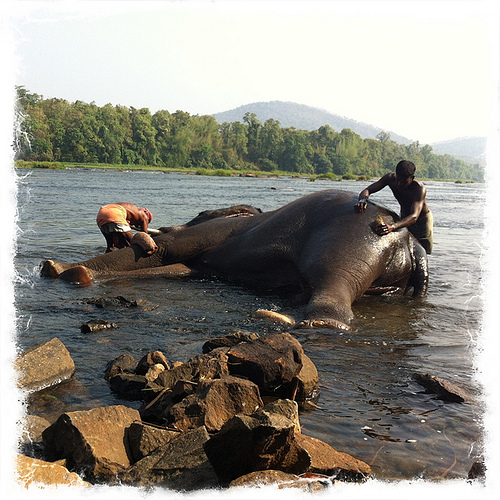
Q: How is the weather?
A: It is clear.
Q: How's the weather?
A: It is clear.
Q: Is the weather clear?
A: Yes, it is clear.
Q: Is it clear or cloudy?
A: It is clear.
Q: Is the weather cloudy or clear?
A: It is clear.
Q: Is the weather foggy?
A: No, it is clear.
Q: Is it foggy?
A: No, it is clear.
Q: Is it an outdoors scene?
A: Yes, it is outdoors.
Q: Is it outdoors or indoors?
A: It is outdoors.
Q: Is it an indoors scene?
A: No, it is outdoors.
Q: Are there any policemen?
A: No, there are no policemen.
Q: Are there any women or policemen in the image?
A: No, there are no policemen or women.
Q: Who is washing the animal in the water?
A: The man is washing the elephant.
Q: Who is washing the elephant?
A: The man is washing the elephant.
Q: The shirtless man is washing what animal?
A: The man is washing the elephant.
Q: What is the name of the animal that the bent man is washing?
A: The animal is an elephant.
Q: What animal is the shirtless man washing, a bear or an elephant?
A: The man is washing an elephant.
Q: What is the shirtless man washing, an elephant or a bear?
A: The man is washing an elephant.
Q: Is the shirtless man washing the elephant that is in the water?
A: Yes, the man is washing the elephant.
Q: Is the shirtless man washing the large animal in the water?
A: Yes, the man is washing the elephant.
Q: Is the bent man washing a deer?
A: No, the man is washing the elephant.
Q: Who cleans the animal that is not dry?
A: The man cleans the elephant.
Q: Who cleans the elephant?
A: The man cleans the elephant.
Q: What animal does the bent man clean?
A: The man cleans the elephant.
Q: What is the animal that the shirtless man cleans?
A: The animal is an elephant.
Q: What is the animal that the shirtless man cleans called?
A: The animal is an elephant.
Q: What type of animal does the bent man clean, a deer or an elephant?
A: The man cleans an elephant.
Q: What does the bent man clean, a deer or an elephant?
A: The man cleans an elephant.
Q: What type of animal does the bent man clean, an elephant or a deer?
A: The man cleans an elephant.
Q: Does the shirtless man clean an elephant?
A: Yes, the man cleans an elephant.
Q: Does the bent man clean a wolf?
A: No, the man cleans an elephant.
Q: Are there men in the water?
A: Yes, there is a man in the water.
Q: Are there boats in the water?
A: No, there is a man in the water.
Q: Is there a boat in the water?
A: No, there is a man in the water.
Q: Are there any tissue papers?
A: No, there are no tissue papers.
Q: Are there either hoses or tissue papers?
A: No, there are no tissue papers or hoses.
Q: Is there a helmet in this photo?
A: No, there are no helmets.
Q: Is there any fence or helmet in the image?
A: No, there are no helmets or fences.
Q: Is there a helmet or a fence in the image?
A: No, there are no helmets or fences.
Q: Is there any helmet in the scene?
A: No, there are no helmets.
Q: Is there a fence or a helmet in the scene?
A: No, there are no helmets or fences.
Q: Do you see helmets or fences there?
A: No, there are no helmets or fences.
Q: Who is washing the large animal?
A: The man is washing the elephant.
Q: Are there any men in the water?
A: Yes, there is a man in the water.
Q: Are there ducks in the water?
A: No, there is a man in the water.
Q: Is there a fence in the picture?
A: No, there are no fences.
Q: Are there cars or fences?
A: No, there are no fences or cars.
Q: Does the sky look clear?
A: Yes, the sky is clear.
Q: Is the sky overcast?
A: No, the sky is clear.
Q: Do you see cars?
A: No, there are no cars.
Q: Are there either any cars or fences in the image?
A: No, there are no cars or fences.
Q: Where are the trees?
A: The trees are on the shore.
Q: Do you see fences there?
A: No, there are no fences.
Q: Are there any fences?
A: No, there are no fences.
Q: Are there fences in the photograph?
A: No, there are no fences.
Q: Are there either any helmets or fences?
A: No, there are no fences or helmets.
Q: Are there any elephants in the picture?
A: Yes, there is an elephant.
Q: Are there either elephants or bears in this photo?
A: Yes, there is an elephant.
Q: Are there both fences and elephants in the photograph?
A: No, there is an elephant but no fences.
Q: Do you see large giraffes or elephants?
A: Yes, there is a large elephant.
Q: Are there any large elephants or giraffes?
A: Yes, there is a large elephant.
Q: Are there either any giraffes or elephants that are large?
A: Yes, the elephant is large.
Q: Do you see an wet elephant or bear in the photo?
A: Yes, there is a wet elephant.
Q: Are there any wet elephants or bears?
A: Yes, there is a wet elephant.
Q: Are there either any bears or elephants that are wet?
A: Yes, the elephant is wet.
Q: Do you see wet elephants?
A: Yes, there is a wet elephant.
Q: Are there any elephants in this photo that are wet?
A: Yes, there is an elephant that is wet.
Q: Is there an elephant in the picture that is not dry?
A: Yes, there is a wet elephant.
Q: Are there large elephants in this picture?
A: Yes, there is a large elephant.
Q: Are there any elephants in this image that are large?
A: Yes, there is an elephant that is large.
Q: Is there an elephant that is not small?
A: Yes, there is a large elephant.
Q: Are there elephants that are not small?
A: Yes, there is a large elephant.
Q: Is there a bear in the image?
A: No, there are no bears.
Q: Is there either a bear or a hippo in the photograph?
A: No, there are no bears or hippoes.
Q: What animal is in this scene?
A: The animal is an elephant.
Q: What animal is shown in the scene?
A: The animal is an elephant.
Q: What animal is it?
A: The animal is an elephant.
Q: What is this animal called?
A: This is an elephant.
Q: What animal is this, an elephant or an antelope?
A: This is an elephant.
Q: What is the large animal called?
A: The animal is an elephant.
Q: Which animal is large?
A: The animal is an elephant.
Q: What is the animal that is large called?
A: The animal is an elephant.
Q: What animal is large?
A: The animal is an elephant.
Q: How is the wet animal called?
A: The animal is an elephant.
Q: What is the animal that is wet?
A: The animal is an elephant.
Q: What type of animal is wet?
A: The animal is an elephant.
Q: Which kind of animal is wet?
A: The animal is an elephant.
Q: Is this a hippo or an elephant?
A: This is an elephant.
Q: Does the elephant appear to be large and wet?
A: Yes, the elephant is large and wet.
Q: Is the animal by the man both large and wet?
A: Yes, the elephant is large and wet.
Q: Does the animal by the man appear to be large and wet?
A: Yes, the elephant is large and wet.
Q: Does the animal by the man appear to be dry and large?
A: No, the elephant is large but wet.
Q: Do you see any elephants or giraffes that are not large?
A: No, there is an elephant but it is large.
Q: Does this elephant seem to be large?
A: Yes, the elephant is large.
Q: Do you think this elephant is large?
A: Yes, the elephant is large.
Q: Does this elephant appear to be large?
A: Yes, the elephant is large.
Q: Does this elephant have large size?
A: Yes, the elephant is large.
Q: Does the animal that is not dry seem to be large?
A: Yes, the elephant is large.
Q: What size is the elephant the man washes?
A: The elephant is large.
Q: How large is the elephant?
A: The elephant is large.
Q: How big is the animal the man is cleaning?
A: The elephant is large.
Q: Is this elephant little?
A: No, the elephant is large.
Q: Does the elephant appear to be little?
A: No, the elephant is large.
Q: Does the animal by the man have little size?
A: No, the elephant is large.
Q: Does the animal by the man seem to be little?
A: No, the elephant is large.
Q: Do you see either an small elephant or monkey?
A: No, there is an elephant but it is large.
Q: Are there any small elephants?
A: No, there is an elephant but it is large.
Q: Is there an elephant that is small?
A: No, there is an elephant but it is large.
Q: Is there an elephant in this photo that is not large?
A: No, there is an elephant but it is large.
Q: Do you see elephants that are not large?
A: No, there is an elephant but it is large.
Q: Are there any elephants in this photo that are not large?
A: No, there is an elephant but it is large.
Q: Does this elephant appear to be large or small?
A: The elephant is large.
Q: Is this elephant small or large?
A: The elephant is large.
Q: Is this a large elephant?
A: Yes, this is a large elephant.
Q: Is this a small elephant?
A: No, this is a large elephant.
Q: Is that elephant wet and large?
A: Yes, the elephant is wet and large.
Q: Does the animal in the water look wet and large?
A: Yes, the elephant is wet and large.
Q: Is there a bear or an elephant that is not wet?
A: No, there is an elephant but it is wet.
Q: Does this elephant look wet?
A: Yes, the elephant is wet.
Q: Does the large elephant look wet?
A: Yes, the elephant is wet.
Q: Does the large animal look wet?
A: Yes, the elephant is wet.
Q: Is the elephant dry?
A: No, the elephant is wet.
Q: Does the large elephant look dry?
A: No, the elephant is wet.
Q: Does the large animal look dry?
A: No, the elephant is wet.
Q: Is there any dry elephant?
A: No, there is an elephant but it is wet.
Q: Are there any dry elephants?
A: No, there is an elephant but it is wet.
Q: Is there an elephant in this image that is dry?
A: No, there is an elephant but it is wet.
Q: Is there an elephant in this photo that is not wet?
A: No, there is an elephant but it is wet.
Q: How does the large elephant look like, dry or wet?
A: The elephant is wet.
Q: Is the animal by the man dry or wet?
A: The elephant is wet.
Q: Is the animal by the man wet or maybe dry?
A: The elephant is wet.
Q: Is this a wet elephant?
A: Yes, this is a wet elephant.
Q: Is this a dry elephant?
A: No, this is a wet elephant.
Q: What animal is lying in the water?
A: The elephant is lying in the water.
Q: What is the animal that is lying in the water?
A: The animal is an elephant.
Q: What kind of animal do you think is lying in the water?
A: The animal is an elephant.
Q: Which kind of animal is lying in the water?
A: The animal is an elephant.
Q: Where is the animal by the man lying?
A: The elephant is lying in the water.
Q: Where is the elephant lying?
A: The elephant is lying in the water.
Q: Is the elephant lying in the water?
A: Yes, the elephant is lying in the water.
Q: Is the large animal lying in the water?
A: Yes, the elephant is lying in the water.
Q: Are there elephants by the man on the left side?
A: Yes, there is an elephant by the man.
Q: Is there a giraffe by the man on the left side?
A: No, there is an elephant by the man.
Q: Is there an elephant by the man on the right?
A: Yes, there is an elephant by the man.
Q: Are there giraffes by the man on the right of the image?
A: No, there is an elephant by the man.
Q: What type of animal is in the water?
A: The animal is an elephant.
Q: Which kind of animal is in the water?
A: The animal is an elephant.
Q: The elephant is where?
A: The elephant is in the water.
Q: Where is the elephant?
A: The elephant is in the water.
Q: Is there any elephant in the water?
A: Yes, there is an elephant in the water.